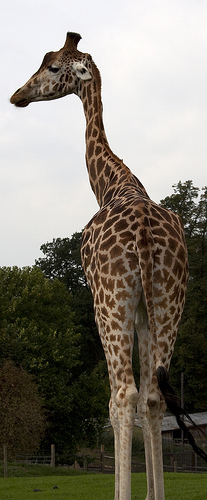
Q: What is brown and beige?
A: Giraffe.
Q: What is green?
A: Grass.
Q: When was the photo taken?
A: Daytime.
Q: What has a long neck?
A: A giraffe.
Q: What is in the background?
A: Trees.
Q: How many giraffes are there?
A: One.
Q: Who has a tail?
A: The giraffe.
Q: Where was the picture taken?
A: In the grass.